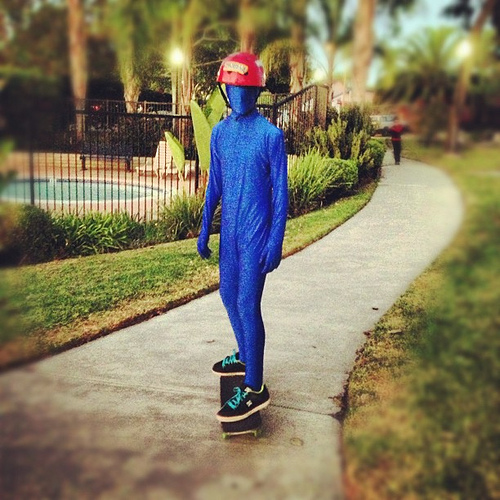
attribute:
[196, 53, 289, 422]
man — blue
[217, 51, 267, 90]
helmet — red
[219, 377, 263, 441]
skateboard — black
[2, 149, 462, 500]
sidewalk — gray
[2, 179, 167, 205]
pool — in-ground, blue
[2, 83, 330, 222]
fence — black, tall, metal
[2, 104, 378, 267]
bushes — green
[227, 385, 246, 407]
laces — blue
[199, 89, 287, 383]
bodysuit — blue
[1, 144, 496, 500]
ground — grass, patchy